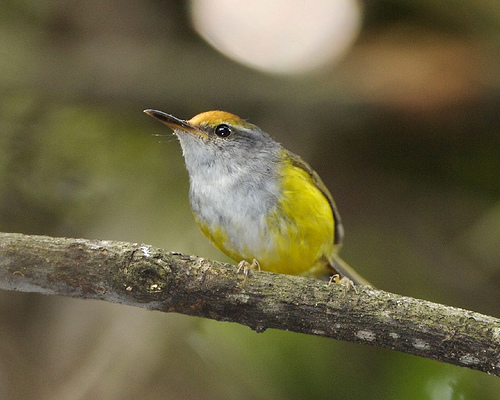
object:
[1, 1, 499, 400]
an outdoor image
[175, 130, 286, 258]
white patch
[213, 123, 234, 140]
round bird eye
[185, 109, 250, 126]
orange top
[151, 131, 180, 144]
little whiskers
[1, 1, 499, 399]
daytime scene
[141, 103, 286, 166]
bird is looking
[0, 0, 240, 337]
left side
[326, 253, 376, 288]
birds tail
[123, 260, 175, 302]
small knot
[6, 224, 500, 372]
tree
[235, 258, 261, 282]
claw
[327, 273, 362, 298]
claw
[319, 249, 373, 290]
feathers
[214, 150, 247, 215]
feathers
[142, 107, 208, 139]
beak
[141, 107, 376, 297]
bird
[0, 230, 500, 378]
branch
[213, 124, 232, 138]
eye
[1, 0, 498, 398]
background